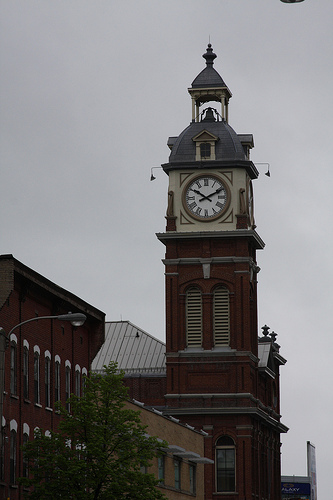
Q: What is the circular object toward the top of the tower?
A: Clock.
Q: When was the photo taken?
A: Daytime.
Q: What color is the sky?
A: White.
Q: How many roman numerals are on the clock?
A: Twelve.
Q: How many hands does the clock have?
A: Two.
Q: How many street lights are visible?
A: One.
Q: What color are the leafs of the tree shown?
A: Green.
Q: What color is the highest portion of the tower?
A: Gray.